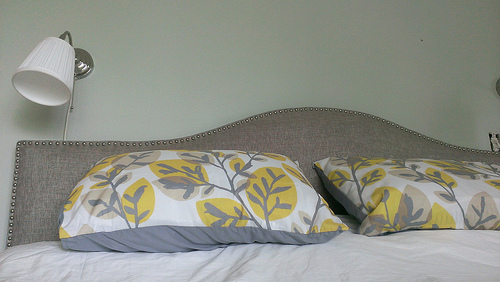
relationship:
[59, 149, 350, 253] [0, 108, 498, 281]
pillow laying on bed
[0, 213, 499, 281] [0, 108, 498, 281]
sheet covers bed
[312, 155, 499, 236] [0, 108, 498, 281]
pillow laying on bed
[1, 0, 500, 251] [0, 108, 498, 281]
wall behind bed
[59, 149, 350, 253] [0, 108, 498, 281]
pillow on top of bed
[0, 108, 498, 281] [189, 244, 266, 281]
bed has lump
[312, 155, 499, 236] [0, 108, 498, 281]
pillow on bed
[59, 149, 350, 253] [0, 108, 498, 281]
pillow on bed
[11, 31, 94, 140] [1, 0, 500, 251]
lamp on wall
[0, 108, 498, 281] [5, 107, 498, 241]
bed has headboard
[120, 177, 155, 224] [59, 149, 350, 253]
leaf on pillow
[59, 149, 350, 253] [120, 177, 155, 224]
pillow has leaf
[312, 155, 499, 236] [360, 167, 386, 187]
pillow has leaf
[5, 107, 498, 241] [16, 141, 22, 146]
headboard has nail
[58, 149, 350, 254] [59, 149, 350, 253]
pillowcase covers pillow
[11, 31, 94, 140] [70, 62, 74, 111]
lamp has chain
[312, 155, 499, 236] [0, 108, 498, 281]
pillow on top of bed